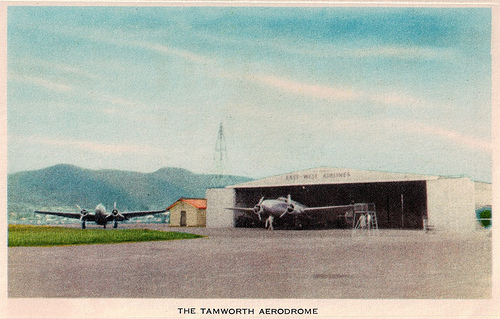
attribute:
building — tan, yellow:
[162, 195, 213, 230]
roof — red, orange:
[169, 191, 207, 211]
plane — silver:
[220, 196, 379, 225]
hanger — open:
[206, 170, 491, 235]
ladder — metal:
[352, 198, 387, 231]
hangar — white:
[200, 168, 491, 239]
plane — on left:
[35, 198, 188, 233]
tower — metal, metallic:
[207, 118, 238, 186]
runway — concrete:
[169, 224, 499, 292]